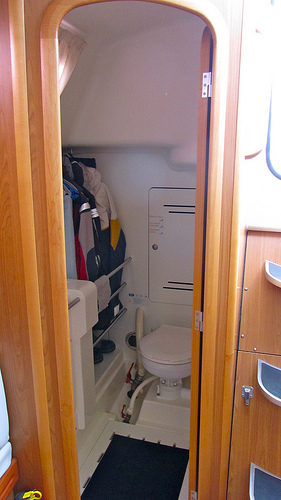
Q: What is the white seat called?
A: Toilet.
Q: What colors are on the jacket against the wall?
A: White, yellow and blue.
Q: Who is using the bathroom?
A: No one.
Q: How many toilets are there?
A: One.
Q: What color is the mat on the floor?
A: Black.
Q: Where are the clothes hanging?
A: Next to the toilet.